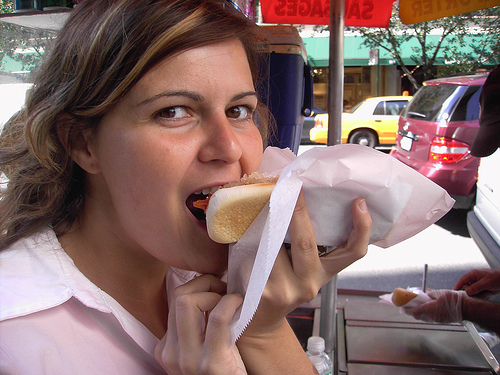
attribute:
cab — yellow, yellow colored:
[308, 87, 415, 150]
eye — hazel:
[154, 99, 196, 129]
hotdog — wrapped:
[196, 165, 407, 245]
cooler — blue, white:
[248, 24, 317, 151]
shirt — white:
[1, 218, 223, 371]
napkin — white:
[214, 134, 456, 336]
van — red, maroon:
[382, 68, 490, 212]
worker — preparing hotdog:
[397, 63, 498, 348]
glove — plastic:
[409, 289, 466, 325]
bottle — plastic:
[299, 332, 338, 373]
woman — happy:
[3, 6, 373, 371]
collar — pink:
[0, 222, 180, 373]